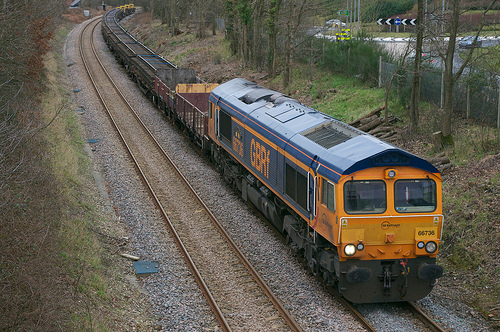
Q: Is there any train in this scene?
A: Yes, there is a train.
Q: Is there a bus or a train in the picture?
A: Yes, there is a train.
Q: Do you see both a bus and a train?
A: No, there is a train but no buses.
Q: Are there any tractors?
A: No, there are no tractors.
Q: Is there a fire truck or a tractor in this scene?
A: No, there are no tractors or fire trucks.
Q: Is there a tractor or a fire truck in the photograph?
A: No, there are no tractors or fire trucks.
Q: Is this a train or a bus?
A: This is a train.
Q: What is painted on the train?
A: The logo is painted on the train.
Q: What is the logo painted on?
A: The logo is painted on the train.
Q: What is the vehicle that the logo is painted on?
A: The vehicle is a train.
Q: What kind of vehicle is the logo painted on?
A: The logo is painted on the train.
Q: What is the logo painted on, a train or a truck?
A: The logo is painted on a train.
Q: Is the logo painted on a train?
A: Yes, the logo is painted on a train.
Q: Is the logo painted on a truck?
A: No, the logo is painted on a train.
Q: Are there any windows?
A: Yes, there is a window.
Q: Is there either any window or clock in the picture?
A: Yes, there is a window.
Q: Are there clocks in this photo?
A: No, there are no clocks.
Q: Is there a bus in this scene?
A: No, there are no buses.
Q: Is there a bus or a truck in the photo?
A: No, there are no buses or trucks.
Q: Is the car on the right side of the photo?
A: Yes, the car is on the right of the image.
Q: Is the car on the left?
A: No, the car is on the right of the image.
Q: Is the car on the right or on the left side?
A: The car is on the right of the image.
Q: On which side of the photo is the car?
A: The car is on the right of the image.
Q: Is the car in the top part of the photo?
A: Yes, the car is in the top of the image.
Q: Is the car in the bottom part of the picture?
A: No, the car is in the top of the image.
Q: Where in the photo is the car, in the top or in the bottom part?
A: The car is in the top of the image.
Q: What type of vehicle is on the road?
A: The vehicle is a car.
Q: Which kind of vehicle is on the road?
A: The vehicle is a car.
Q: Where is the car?
A: The car is on the road.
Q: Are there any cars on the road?
A: Yes, there is a car on the road.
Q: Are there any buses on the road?
A: No, there is a car on the road.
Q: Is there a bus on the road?
A: No, there is a car on the road.